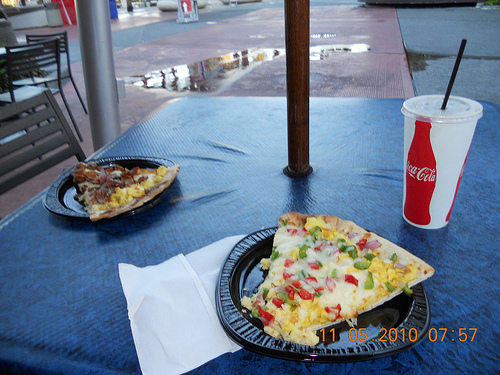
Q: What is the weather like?
A: Rainy.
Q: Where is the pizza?
A: On plastic plates.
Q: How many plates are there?
A: Two.